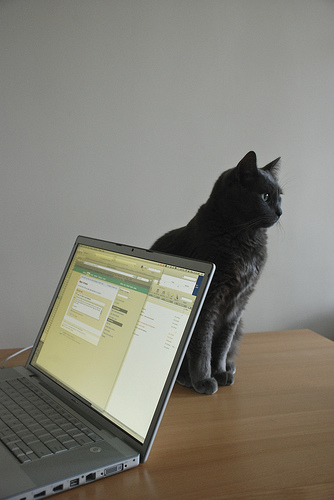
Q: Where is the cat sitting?
A: The table.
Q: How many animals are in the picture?
A: One.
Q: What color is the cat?
A: Gray.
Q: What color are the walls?
A: White.